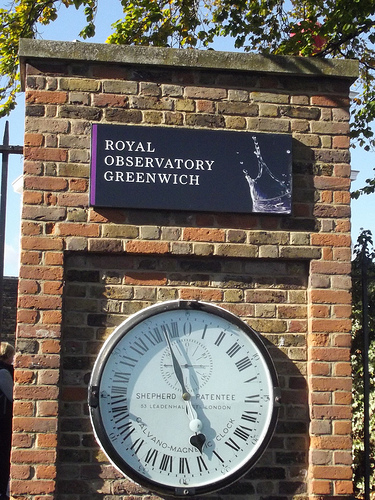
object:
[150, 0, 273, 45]
branches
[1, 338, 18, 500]
person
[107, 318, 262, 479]
number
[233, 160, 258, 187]
ground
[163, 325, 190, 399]
minute hand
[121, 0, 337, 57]
foliage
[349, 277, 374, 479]
fence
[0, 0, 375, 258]
tree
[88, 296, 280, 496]
clock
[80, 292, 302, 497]
face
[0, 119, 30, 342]
fence post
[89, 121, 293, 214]
sign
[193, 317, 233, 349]
roman numerals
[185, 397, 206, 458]
clock hand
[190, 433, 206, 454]
spade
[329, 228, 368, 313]
post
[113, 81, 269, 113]
brick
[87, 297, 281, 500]
border